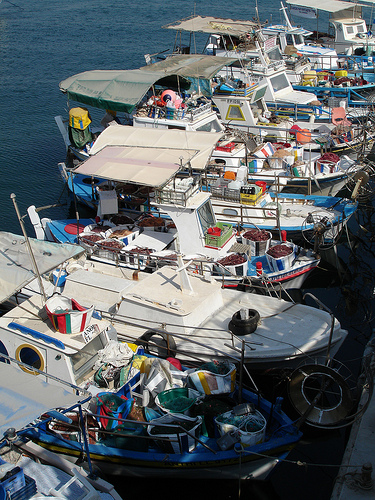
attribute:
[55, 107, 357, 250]
boat — lined, yellow, docked , painted, covered, stiing, white color, white, red, blue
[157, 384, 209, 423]
basket — gray, green, brown, red, white, flipped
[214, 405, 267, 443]
bag — sitting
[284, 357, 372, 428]
ring — metal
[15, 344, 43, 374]
window — trimmed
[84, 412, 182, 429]
pole — metal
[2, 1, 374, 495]
water — rippled, blue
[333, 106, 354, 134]
chair — pink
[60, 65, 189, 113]
canopy — green